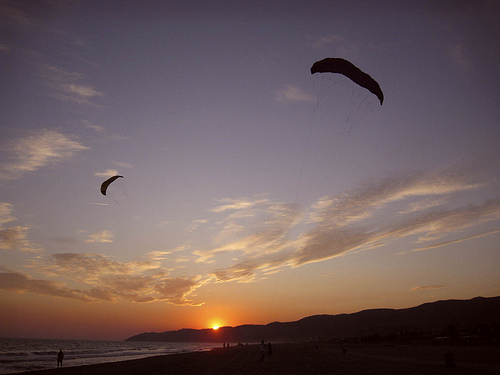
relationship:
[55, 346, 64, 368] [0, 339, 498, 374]
person on beach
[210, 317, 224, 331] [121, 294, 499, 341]
sun setting behind mountains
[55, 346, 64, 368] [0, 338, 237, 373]
person standing by water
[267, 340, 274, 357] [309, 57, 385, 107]
person flying kite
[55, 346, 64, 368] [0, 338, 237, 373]
person standing in front of water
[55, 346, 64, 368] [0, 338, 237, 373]
person standing next to water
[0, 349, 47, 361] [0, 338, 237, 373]
waves in water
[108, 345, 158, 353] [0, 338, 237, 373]
waves in water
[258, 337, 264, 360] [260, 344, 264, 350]
man with vest